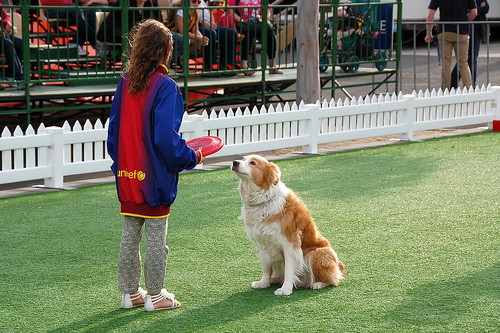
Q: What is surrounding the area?
A: A white fence.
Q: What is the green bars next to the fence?
A: Bleachers.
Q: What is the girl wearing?
A: A jacket.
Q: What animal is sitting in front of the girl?
A: A dog.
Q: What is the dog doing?
A: Sitting and waiting.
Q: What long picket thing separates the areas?
A: Fence.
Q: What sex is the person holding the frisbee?
A: Female.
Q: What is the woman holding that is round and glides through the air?
A: Frisbee.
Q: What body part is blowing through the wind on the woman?
A: Hair.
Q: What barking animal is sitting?
A: Dog.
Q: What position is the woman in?
A: Standing.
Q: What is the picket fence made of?
A: Wood.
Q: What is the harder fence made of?
A: Metal.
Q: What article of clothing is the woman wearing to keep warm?
A: Coat.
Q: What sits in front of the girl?
A: A dog.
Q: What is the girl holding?
A: A frisbee.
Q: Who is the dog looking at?
A: The girl with the frisbee.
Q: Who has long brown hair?
A: The girl.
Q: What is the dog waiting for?
A: The frisbee.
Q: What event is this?
A: A dog competition.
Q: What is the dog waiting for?
A: The woman to command it.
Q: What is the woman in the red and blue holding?
A: A red frisbee.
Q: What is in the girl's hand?
A: A red frisbee.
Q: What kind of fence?
A: Picket.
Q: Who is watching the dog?
A: Spectactors.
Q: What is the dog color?
A: Brown.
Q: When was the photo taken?
A: Day time.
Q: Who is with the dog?
A: The girl.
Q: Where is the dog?
A: Infront of the girl.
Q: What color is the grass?
A: Green.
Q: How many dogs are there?
A: 1.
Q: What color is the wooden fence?
A: White.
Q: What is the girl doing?
A: Standing.